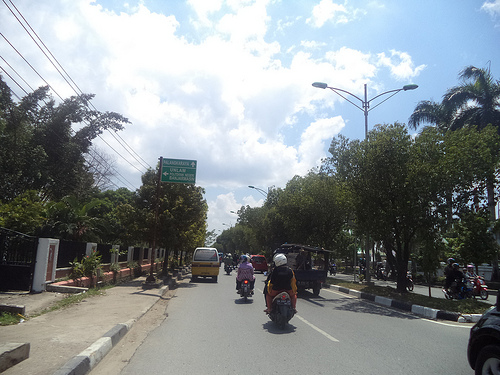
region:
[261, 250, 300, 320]
motorbike passenger wearing white helmet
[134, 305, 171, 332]
missing pavement between sidewalk and street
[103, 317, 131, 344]
gray sidewalk curb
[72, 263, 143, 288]
short red retaining wall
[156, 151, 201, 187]
green directional sign with with letters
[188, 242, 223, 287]
yellow multi-passenger vehicle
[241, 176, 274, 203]
metal streetlamp with light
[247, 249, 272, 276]
red car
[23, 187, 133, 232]
lush green tropical foliage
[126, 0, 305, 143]
sky full of white puffy clouds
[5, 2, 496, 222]
the sky is blue with white clouds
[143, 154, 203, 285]
a green and white directional sign on a pole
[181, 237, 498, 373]
vehicular traffic is on the street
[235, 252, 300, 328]
motorcycles are moving down the street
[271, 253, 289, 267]
the person has a white helmet on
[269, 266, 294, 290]
the person is wearing a black shirt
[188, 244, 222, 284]
the van is yellow and white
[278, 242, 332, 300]
a truck is carrying items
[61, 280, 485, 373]
the curb is black and white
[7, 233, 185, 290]
a fence is on the side of the road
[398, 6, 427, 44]
part of the sky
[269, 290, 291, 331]
part of a wheel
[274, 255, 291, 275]
part of a helmet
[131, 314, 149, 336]
edge of a road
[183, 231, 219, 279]
back of a van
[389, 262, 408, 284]
stem of a tree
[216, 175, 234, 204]
part of a cloud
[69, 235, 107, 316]
part of a plant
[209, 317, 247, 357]
the road is made of asphalt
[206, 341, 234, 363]
the road is made of asphalt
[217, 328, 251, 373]
the road is made of asphalt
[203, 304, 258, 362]
the road is made of asphalt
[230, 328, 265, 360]
the road is made of asphalt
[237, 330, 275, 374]
the road is made of asphalt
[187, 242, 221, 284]
this is a vehicle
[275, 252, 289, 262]
this is a helmet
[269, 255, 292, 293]
the man is on the motorbike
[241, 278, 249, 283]
the rear light is on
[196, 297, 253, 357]
the road is tarmacked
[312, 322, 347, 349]
white strip is on the middle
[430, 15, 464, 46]
the sky is blue in color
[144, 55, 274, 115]
the clouds are many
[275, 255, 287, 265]
the helmet is white in color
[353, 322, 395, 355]
the road is clean